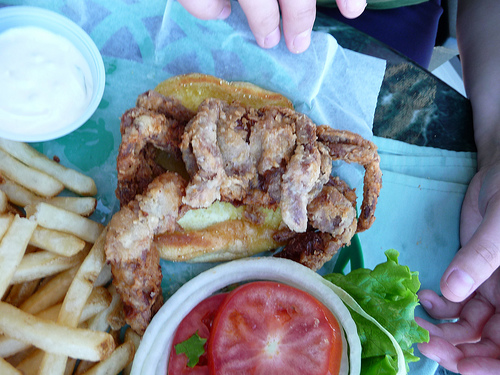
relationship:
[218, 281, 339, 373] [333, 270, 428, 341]
tomato on lettuce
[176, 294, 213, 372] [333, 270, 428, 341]
tomato on lettuce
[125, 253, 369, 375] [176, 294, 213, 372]
onion around tomato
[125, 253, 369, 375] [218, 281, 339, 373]
onion around tomato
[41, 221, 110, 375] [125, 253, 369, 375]
french fry beside onion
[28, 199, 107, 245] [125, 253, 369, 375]
french fry beside onion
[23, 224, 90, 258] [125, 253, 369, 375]
french fry beside onion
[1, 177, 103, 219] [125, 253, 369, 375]
french fry beside onion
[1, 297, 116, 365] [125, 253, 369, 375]
french fry beside onion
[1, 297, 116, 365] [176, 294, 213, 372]
french fry beside tomato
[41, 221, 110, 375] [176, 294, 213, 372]
french fry beside tomato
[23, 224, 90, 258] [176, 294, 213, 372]
french fry beside tomato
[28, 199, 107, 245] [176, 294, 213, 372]
french fry beside tomato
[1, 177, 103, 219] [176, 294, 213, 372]
french fry beside tomato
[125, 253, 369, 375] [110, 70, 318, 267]
onion off sandwich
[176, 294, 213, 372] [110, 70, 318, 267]
tomato off sandwich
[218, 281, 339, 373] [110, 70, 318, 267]
tomato off sandwich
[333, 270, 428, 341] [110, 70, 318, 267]
lettuce off sandwich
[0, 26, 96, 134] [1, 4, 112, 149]
condiment in a cup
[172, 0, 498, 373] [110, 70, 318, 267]
person will eat sandwich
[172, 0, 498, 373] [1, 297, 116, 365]
person will eat french fry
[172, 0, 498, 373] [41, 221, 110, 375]
person will eat french fry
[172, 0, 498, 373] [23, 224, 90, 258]
person will eat french fry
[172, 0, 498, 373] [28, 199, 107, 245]
person will eat french fry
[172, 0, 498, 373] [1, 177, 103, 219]
person will eat french fry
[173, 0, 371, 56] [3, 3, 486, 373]
hand on table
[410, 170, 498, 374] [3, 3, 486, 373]
hand on table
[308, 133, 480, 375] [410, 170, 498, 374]
napkin under hand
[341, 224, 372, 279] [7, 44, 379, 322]
edge of a dish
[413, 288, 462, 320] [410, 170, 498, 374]
finger on hand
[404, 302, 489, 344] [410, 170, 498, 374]
finger on hand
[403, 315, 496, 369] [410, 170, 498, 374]
finger on hand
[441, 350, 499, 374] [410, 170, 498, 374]
finger on hand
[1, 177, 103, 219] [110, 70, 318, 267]
french fry next to a sandwich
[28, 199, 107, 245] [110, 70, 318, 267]
french fry next to a sandwich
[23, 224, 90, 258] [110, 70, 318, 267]
french fry next to a sandwich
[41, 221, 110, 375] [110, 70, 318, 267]
french fry next to a sandwich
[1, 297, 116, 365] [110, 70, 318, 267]
french fry next to a sandwich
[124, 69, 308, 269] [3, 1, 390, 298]
bun on a wrapper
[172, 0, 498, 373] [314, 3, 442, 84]
person wearing pants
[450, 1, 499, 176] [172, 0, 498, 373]
arm of person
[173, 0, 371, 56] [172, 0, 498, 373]
hand of person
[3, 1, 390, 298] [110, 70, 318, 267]
wrapper holds sandwich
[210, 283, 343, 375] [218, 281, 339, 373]
slice of tomato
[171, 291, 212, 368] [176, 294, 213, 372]
slice of tomato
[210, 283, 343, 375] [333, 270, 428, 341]
slice on top of lettuce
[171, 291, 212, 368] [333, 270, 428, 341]
slice on top of lettuce